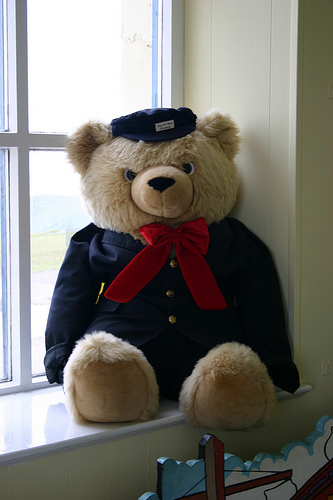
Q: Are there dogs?
A: No, there are no dogs.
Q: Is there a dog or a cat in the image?
A: No, there are no dogs or cats.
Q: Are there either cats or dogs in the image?
A: No, there are no dogs or cats.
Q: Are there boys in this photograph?
A: No, there are no boys.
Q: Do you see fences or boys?
A: No, there are no boys or fences.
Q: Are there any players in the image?
A: No, there are no players.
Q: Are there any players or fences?
A: No, there are no players or fences.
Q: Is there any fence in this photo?
A: No, there are no fences.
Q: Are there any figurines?
A: No, there are no figurines.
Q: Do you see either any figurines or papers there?
A: No, there are no figurines or papers.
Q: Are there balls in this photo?
A: No, there are no balls.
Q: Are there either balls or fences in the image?
A: No, there are no balls or fences.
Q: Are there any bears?
A: Yes, there is a bear.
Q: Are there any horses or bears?
A: Yes, there is a bear.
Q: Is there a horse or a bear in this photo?
A: Yes, there is a bear.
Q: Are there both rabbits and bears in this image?
A: No, there is a bear but no rabbits.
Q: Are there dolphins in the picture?
A: No, there are no dolphins.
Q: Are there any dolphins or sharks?
A: No, there are no dolphins or sharks.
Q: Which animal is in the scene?
A: The animal is a bear.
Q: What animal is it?
A: The animal is a bear.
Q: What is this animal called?
A: This is a bear.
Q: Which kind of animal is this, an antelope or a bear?
A: This is a bear.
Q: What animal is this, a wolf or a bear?
A: This is a bear.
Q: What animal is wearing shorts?
A: The bear is wearing shorts.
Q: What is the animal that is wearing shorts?
A: The animal is a bear.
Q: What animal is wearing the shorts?
A: The animal is a bear.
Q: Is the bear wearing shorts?
A: Yes, the bear is wearing shorts.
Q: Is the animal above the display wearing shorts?
A: Yes, the bear is wearing shorts.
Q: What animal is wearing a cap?
A: The bear is wearing a cap.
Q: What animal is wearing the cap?
A: The bear is wearing a cap.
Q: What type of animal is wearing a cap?
A: The animal is a bear.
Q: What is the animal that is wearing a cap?
A: The animal is a bear.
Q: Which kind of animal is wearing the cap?
A: The animal is a bear.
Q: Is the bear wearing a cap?
A: Yes, the bear is wearing a cap.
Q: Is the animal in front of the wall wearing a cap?
A: Yes, the bear is wearing a cap.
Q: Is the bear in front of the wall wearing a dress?
A: No, the bear is wearing a cap.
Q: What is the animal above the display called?
A: The animal is a bear.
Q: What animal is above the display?
A: The animal is a bear.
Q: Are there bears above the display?
A: Yes, there is a bear above the display.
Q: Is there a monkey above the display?
A: No, there is a bear above the display.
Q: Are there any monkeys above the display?
A: No, there is a bear above the display.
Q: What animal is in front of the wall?
A: The bear is in front of the wall.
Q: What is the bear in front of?
A: The bear is in front of the wall.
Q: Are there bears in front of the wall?
A: Yes, there is a bear in front of the wall.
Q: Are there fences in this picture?
A: No, there are no fences.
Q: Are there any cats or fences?
A: No, there are no fences or cats.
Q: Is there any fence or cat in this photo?
A: No, there are no fences or cats.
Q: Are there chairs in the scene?
A: No, there are no chairs.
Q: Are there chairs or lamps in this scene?
A: No, there are no chairs or lamps.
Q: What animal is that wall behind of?
A: The wall is behind the bear.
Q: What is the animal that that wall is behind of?
A: The animal is a bear.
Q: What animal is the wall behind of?
A: The wall is behind the bear.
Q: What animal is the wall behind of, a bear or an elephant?
A: The wall is behind a bear.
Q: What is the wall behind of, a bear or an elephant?
A: The wall is behind a bear.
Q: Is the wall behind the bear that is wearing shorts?
A: Yes, the wall is behind the bear.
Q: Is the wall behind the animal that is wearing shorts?
A: Yes, the wall is behind the bear.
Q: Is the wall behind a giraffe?
A: No, the wall is behind the bear.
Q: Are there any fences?
A: No, there are no fences.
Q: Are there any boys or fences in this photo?
A: No, there are no fences or boys.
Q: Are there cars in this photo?
A: No, there are no cars.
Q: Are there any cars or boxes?
A: No, there are no cars or boxes.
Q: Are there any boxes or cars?
A: No, there are no cars or boxes.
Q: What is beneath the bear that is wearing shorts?
A: The display is beneath the bear.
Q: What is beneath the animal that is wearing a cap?
A: The display is beneath the bear.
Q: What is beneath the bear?
A: The display is beneath the bear.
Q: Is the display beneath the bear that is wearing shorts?
A: Yes, the display is beneath the bear.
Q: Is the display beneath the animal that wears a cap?
A: Yes, the display is beneath the bear.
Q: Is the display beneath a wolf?
A: No, the display is beneath the bear.